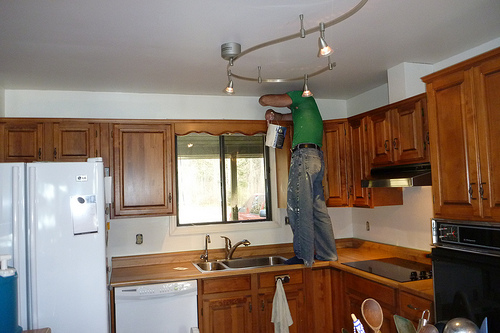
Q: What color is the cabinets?
A: Brown.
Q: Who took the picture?
A: The home owner.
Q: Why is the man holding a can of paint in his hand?
A: To paint.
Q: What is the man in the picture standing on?
A: He is standing on the edge of the sink.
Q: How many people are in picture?
A: One.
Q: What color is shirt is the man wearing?
A: Green.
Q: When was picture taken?
A: During the day.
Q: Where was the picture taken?
A: In the kitchen.